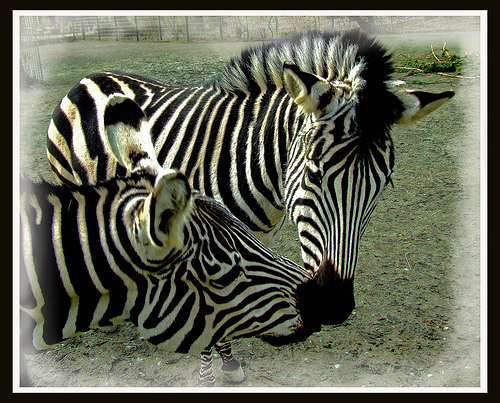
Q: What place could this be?
A: It is a yard.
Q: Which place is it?
A: It is a yard.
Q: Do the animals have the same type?
A: Yes, all the animals are zebras.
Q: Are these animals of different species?
A: No, all the animals are zebras.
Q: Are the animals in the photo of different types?
A: No, all the animals are zebras.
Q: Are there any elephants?
A: No, there are no elephants.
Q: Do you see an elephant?
A: No, there are no elephants.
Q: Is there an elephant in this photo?
A: No, there are no elephants.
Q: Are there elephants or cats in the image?
A: No, there are no elephants or cats.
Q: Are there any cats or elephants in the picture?
A: No, there are no elephants or cats.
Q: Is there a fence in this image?
A: Yes, there is a fence.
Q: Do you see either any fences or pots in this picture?
A: Yes, there is a fence.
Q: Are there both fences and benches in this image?
A: No, there is a fence but no benches.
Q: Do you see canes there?
A: No, there are no canes.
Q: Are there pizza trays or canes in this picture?
A: No, there are no canes or pizza trays.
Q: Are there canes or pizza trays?
A: No, there are no canes or pizza trays.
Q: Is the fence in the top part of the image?
A: Yes, the fence is in the top of the image.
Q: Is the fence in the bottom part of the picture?
A: No, the fence is in the top of the image.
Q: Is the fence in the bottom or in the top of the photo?
A: The fence is in the top of the image.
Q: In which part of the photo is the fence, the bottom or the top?
A: The fence is in the top of the image.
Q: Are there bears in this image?
A: No, there are no bears.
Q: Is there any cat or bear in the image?
A: No, there are no bears or cats.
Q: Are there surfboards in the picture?
A: No, there are no surfboards.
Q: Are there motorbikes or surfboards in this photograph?
A: No, there are no surfboards or motorbikes.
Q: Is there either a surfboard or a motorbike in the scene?
A: No, there are no surfboards or motorcycles.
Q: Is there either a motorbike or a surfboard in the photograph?
A: No, there are no surfboards or motorcycles.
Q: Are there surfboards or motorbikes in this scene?
A: No, there are no surfboards or motorbikes.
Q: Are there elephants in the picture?
A: No, there are no elephants.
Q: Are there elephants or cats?
A: No, there are no elephants or cats.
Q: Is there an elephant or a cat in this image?
A: No, there are no elephants or cats.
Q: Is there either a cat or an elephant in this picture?
A: No, there are no elephants or cats.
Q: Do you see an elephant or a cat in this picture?
A: No, there are no elephants or cats.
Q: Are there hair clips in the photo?
A: No, there are no hair clips.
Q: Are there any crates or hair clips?
A: No, there are no hair clips or crates.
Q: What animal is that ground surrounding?
A: The ground is surrounding the zebras.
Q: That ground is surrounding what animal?
A: The ground is surrounding the zebras.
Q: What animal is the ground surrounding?
A: The ground is surrounding the zebras.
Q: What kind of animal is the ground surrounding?
A: The ground is surrounding the zebras.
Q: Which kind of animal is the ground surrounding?
A: The ground is surrounding the zebras.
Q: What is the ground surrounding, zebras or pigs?
A: The ground is surrounding zebras.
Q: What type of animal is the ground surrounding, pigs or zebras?
A: The ground is surrounding zebras.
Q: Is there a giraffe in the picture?
A: No, there are no giraffes.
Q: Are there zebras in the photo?
A: Yes, there is a zebra.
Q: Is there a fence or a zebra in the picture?
A: Yes, there is a zebra.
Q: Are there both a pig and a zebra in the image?
A: No, there is a zebra but no pigs.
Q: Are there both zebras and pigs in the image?
A: No, there is a zebra but no pigs.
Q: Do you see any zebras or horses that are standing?
A: Yes, the zebra is standing.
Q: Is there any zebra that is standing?
A: Yes, there is a zebra that is standing.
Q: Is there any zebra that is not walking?
A: Yes, there is a zebra that is standing.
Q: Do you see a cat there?
A: No, there are no cats.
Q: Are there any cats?
A: No, there are no cats.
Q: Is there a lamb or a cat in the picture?
A: No, there are no cats or lambs.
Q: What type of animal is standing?
A: The animal is a zebra.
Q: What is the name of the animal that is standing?
A: The animal is a zebra.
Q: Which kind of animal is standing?
A: The animal is a zebra.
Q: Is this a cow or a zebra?
A: This is a zebra.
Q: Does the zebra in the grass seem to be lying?
A: No, the zebra is standing.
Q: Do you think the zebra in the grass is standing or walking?
A: The zebra is standing.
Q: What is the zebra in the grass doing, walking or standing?
A: The zebra is standing.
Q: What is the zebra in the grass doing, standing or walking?
A: The zebra is standing.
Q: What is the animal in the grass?
A: The animal is a zebra.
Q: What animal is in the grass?
A: The animal is a zebra.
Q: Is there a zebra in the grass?
A: Yes, there is a zebra in the grass.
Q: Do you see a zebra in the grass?
A: Yes, there is a zebra in the grass.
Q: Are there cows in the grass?
A: No, there is a zebra in the grass.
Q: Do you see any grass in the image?
A: Yes, there is grass.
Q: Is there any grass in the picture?
A: Yes, there is grass.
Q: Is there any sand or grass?
A: Yes, there is grass.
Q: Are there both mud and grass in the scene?
A: No, there is grass but no mud.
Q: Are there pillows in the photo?
A: No, there are no pillows.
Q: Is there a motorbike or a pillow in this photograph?
A: No, there are no pillows or motorcycles.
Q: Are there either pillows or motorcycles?
A: No, there are no pillows or motorcycles.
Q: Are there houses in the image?
A: No, there are no houses.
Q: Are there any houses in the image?
A: No, there are no houses.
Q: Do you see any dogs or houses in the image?
A: No, there are no houses or dogs.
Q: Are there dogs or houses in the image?
A: No, there are no houses or dogs.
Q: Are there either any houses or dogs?
A: No, there are no houses or dogs.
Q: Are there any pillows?
A: No, there are no pillows.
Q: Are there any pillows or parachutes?
A: No, there are no pillows or parachutes.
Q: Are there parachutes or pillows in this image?
A: No, there are no pillows or parachutes.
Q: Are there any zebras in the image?
A: Yes, there are zebras.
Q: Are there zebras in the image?
A: Yes, there are zebras.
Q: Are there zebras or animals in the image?
A: Yes, there are zebras.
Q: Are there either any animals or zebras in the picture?
A: Yes, there are zebras.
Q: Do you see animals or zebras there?
A: Yes, there are zebras.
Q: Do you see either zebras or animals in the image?
A: Yes, there are zebras.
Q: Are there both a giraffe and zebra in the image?
A: No, there are zebras but no giraffes.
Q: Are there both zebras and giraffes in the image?
A: No, there are zebras but no giraffes.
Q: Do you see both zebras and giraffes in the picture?
A: No, there are zebras but no giraffes.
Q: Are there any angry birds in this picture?
A: No, there are no angry birds.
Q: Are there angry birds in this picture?
A: No, there are no angry birds.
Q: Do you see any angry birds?
A: No, there are no angry birds.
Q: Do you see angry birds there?
A: No, there are no angry birds.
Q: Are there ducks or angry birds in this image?
A: No, there are no angry birds or ducks.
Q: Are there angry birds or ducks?
A: No, there are no angry birds or ducks.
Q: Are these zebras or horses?
A: These are zebras.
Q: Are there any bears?
A: No, there are no bears.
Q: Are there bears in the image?
A: No, there are no bears.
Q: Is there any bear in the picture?
A: No, there are no bears.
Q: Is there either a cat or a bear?
A: No, there are no bears or cats.